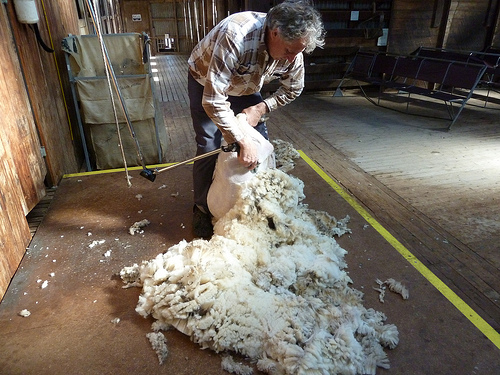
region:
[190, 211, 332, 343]
Animal Fur that is being gathered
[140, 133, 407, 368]
Sheep is being cut for fur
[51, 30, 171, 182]
Brown bag for fur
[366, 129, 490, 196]
Wooden old floor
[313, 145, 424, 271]
Wooden old floor with yellow line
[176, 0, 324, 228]
Man bending over shaving sheep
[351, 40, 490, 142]
Set of chairs in a row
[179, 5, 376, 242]
Man wears checker board shirt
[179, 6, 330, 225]
Man wears dark blue jeans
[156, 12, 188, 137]
Wooden entrance hallway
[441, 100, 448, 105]
part of a chair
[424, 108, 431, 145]
edge of a chair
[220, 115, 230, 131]
part of a shirt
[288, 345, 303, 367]
part of a sheep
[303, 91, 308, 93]
part of an elbow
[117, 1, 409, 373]
Man trimming the wool off a sheep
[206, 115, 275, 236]
Sheep getting his wool shaved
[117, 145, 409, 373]
Large pile of sheep wool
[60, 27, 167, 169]
Tan cloth receptical with metal supports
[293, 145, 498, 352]
Painted yellow line on the floor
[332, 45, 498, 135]
Rows of dark metal seats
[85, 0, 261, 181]
Metal tool for shaving sheep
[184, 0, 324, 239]
Man wearing a plaid shirt and gray pants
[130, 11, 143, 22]
White and black wall sign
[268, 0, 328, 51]
Head of gray hair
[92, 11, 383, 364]
man shaving a sheep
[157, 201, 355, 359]
white sheep wool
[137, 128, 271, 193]
man using an electrical shaver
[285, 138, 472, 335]
yellow line on floor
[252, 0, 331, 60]
man with grey and white hair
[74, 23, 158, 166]
tan fabric bin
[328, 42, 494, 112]
brown and silver chairs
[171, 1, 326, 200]
man wearing a plaid shirt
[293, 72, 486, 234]
large wooden floor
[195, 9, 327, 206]
sunlight shining on man and sheep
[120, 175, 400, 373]
White wool all over the ground.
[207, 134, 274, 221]
A white bag a man is holding with wool in it.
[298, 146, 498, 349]
A yellow line in front of a man.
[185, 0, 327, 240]
A man with grey hair bending over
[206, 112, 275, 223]
A sheep in a man's hands being sheered.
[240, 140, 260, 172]
The right hand of a man sheering sheep.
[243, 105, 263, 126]
The left hand of a man sheering sheep.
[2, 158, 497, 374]
The brown floor inside the yellow lines.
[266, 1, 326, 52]
Grey and white hair of a man sheering sheep.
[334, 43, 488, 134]
Front row of brown and grey seats.